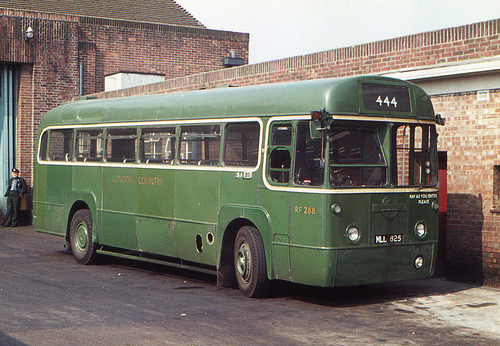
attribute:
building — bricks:
[1, 7, 499, 284]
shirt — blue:
[3, 170, 20, 200]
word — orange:
[291, 204, 316, 217]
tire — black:
[63, 188, 108, 249]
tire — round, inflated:
[225, 220, 275, 300]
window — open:
[264, 142, 296, 185]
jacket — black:
[3, 172, 35, 209]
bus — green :
[37, 75, 437, 290]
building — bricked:
[0, 0, 260, 215]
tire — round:
[234, 221, 259, 298]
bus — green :
[24, 42, 456, 298]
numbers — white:
[373, 91, 403, 111]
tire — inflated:
[63, 204, 100, 269]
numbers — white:
[372, 91, 398, 110]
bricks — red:
[34, 24, 410, 121]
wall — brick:
[48, 80, 498, 312]